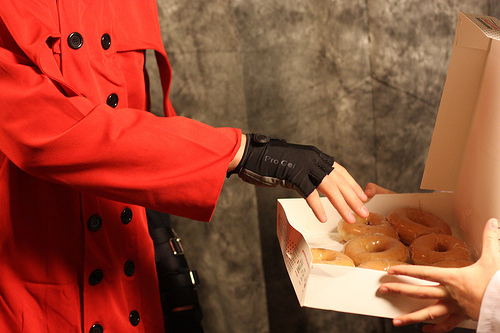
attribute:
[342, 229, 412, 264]
donut — glazed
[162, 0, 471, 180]
wall — brown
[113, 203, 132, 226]
button — black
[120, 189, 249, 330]
purse — black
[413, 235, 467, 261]
donuts — glazed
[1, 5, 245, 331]
jacket — red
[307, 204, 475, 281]
donuts — glazed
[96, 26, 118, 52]
button — black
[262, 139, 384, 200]
glove — black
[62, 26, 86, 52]
button — black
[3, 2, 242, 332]
coat — fancy, red, trench coat, trench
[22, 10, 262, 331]
coat — red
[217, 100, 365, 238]
hand — black, gloved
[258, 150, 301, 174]
text — Pro Cel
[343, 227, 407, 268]
donuts — shiny, glazed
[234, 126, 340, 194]
glove — black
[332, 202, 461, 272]
donuts — glazed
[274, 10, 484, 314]
box — cardboard, Krispy Kreme, big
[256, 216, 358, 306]
box — donut